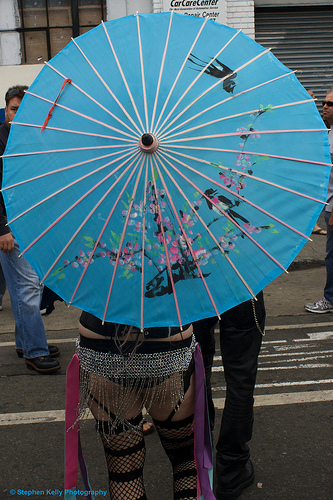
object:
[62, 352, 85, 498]
ribbon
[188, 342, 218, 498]
ribbon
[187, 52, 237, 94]
bird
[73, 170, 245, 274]
flower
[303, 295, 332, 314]
shoe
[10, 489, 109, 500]
lettering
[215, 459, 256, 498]
black shoes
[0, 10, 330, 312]
striped shirt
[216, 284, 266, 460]
pants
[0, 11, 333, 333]
umbrella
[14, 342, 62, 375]
shoes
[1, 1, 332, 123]
building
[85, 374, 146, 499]
leg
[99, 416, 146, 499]
fishnet stockings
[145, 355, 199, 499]
back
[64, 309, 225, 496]
woman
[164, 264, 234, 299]
part